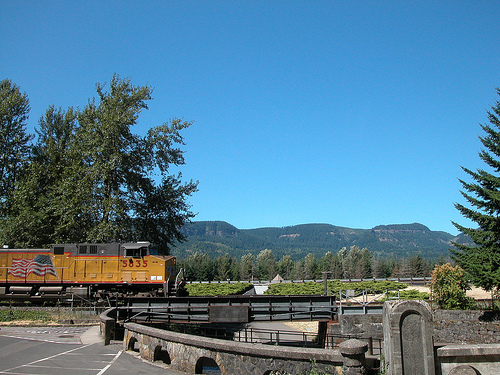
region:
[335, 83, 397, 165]
par tof a sky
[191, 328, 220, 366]
edge of a line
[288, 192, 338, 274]
par tof a hill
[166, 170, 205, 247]
par tof a tree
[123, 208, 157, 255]
part of a windoew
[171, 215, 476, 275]
a large mountain range.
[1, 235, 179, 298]
A train traveling down tracks.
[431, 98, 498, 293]
A tall pine tree.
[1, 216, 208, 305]
a yellow train engine.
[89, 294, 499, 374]
a small train bridge.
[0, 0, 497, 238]
a clear blue sky.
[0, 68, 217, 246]
a tall leaf filled tree.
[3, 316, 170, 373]
a paved parking lot.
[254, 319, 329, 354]
a river below a bridge.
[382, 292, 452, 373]
a tall cement pillar.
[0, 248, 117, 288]
this is an american flag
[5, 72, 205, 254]
these are trees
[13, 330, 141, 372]
this is a road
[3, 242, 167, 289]
this is train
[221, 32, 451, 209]
this is the sky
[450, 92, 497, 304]
this is a tree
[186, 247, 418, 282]
these are trees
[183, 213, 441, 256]
these are hills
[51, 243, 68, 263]
this is train window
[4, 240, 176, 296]
this is a train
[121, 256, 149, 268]
this is a number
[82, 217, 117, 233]
this is a green leaves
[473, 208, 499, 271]
this is a green leaves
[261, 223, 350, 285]
this is a mountain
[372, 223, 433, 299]
this is a mountain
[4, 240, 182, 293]
this is a yellow train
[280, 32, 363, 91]
this is the sky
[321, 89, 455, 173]
the sky is blue in color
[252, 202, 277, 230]
the sky has clouds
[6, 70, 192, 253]
these are some trees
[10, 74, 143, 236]
the trees are tall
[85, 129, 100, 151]
the leaves are green in color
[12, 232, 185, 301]
this is a train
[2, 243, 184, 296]
Yellow engine of a train.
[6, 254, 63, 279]
American flag on a yellow train.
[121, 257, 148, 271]
Red number on a yellow train.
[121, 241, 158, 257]
Windows where the train driver sits.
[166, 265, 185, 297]
Stairs on the front of the train.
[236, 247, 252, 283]
evergreen tree behind the train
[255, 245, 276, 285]
evergreen tree behind the train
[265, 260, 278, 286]
evergreen tree behind the train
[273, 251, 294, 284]
evergreen tree behind the train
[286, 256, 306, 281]
evergreen tree behind the train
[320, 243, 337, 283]
evergreen tree behind the train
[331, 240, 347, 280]
evergreen tree behind the train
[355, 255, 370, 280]
evergreen tree behind the train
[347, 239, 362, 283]
evergreen tree behind the train